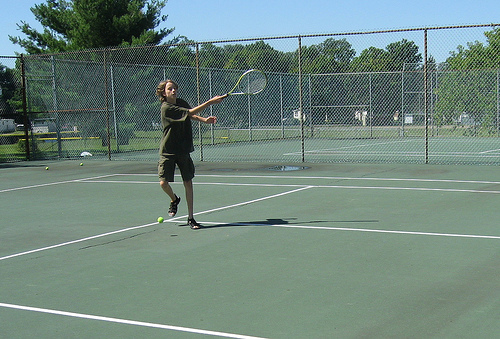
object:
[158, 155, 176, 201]
leg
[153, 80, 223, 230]
boy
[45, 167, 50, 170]
tennis ball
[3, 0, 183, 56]
tree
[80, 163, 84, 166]
tennis ball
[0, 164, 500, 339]
court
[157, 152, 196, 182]
shorts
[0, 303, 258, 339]
lines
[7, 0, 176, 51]
leaves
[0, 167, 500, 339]
sign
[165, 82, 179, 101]
face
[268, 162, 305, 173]
waterpuddle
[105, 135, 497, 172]
tennis court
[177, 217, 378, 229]
shadow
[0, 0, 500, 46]
blue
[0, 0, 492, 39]
sky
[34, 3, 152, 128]
tree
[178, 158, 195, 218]
leg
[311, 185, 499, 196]
line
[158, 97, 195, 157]
shirt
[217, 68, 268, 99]
racket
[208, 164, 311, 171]
puddle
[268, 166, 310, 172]
water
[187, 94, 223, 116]
arms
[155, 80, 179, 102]
head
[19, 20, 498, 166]
fence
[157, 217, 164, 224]
tennis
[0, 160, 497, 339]
tennis court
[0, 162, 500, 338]
ground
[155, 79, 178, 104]
hair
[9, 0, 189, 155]
tree